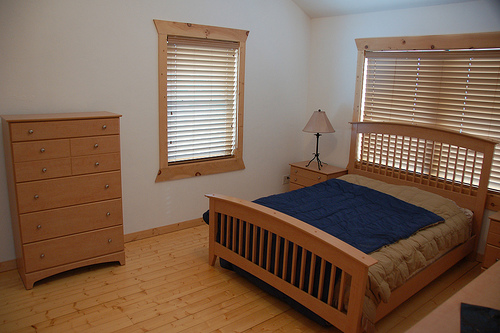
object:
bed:
[205, 119, 499, 332]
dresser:
[0, 112, 128, 292]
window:
[166, 35, 240, 167]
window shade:
[164, 34, 238, 167]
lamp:
[298, 107, 335, 172]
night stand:
[285, 157, 349, 195]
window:
[355, 48, 499, 192]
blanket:
[198, 177, 446, 283]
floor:
[0, 223, 483, 332]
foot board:
[203, 192, 376, 332]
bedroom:
[1, 1, 499, 332]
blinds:
[359, 50, 499, 191]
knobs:
[40, 167, 51, 174]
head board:
[343, 118, 499, 263]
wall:
[0, 0, 309, 273]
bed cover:
[328, 172, 474, 332]